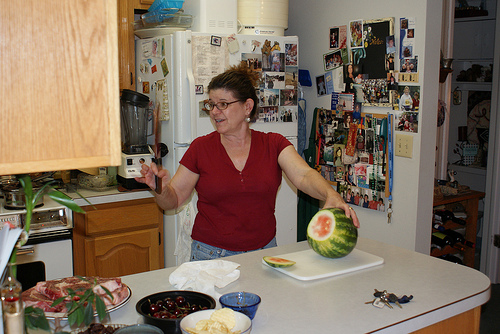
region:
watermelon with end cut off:
[297, 203, 367, 261]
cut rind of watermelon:
[262, 250, 298, 272]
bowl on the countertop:
[214, 286, 267, 316]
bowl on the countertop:
[173, 305, 254, 332]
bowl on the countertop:
[132, 280, 216, 332]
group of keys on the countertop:
[358, 286, 416, 314]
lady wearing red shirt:
[128, 59, 353, 269]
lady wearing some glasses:
[125, 66, 367, 261]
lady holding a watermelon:
[127, 70, 374, 267]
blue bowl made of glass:
[216, 283, 268, 319]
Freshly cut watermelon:
[299, 194, 364, 266]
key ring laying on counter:
[363, 282, 420, 315]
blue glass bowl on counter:
[217, 288, 265, 327]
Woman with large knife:
[134, 62, 300, 248]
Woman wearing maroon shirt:
[177, 62, 286, 249]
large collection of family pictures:
[312, 18, 420, 210]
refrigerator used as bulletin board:
[245, 34, 304, 125]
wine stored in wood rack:
[432, 192, 484, 267]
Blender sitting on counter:
[120, 87, 152, 188]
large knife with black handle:
[150, 100, 167, 199]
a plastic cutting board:
[262, 243, 382, 283]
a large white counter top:
[101, 241, 498, 332]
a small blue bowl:
[221, 289, 266, 317]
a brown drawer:
[82, 199, 161, 232]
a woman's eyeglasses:
[202, 93, 243, 115]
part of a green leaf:
[5, 170, 86, 241]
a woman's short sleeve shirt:
[177, 133, 297, 256]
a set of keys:
[360, 285, 416, 310]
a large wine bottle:
[435, 208, 465, 226]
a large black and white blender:
[115, 91, 161, 191]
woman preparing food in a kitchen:
[1, 3, 493, 333]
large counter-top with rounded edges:
[1, 235, 488, 332]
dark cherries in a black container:
[134, 283, 212, 329]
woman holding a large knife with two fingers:
[131, 98, 169, 197]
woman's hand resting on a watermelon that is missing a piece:
[304, 193, 359, 259]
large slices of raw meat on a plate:
[19, 268, 130, 317]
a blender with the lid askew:
[118, 88, 157, 190]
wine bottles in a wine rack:
[431, 178, 483, 264]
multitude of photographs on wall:
[309, 14, 419, 209]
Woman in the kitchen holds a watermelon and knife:
[132, 59, 360, 259]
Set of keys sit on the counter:
[362, 286, 414, 311]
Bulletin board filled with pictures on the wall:
[304, 107, 393, 214]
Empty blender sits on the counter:
[115, 87, 155, 193]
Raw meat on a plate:
[19, 272, 132, 321]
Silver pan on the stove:
[1, 177, 64, 212]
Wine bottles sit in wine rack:
[428, 195, 477, 265]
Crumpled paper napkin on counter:
[169, 254, 241, 300]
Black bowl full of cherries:
[134, 288, 214, 332]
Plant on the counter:
[20, 274, 114, 332]